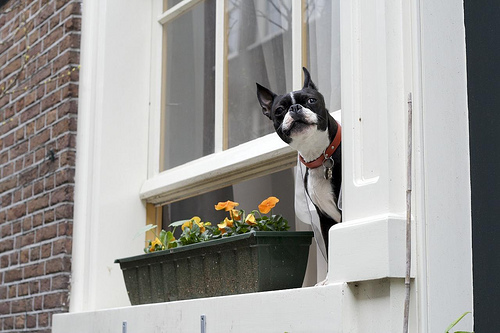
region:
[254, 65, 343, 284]
a black and white boston terrier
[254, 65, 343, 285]
a dog wearing a red collar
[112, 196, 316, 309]
a green planting box filled with flowers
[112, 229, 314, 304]
a green planting box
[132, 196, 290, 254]
orange planted ornamental flowers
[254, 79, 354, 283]
a black and white dog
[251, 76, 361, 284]
a dog looking out the window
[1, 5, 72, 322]
bricks on the building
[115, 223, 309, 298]
a black planter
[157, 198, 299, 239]
yellow flower in the window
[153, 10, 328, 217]
the window on the building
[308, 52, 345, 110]
white curtains inside the window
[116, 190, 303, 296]
a planter in the window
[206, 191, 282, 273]
Orange flowers in a green container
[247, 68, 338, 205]
Boston Terrier with it's head out the window.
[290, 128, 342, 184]
Red dog collar with a silver tag.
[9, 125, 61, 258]
Red brick on side of building.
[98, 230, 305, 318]
Long plastic flower box sitting on window sill.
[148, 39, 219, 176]
Glass window pane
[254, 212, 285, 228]
Green leaves on flowering plant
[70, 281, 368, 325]
Window ledge.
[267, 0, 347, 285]
Sheer white curtain behind window.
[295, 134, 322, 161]
White fur.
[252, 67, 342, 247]
black and white dog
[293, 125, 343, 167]
the dogs red collar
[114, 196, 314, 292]
flowers in a window sil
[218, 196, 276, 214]
the orange flowers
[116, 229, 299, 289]
the green plant holder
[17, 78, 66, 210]
the brick wall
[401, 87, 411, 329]
the stick against the window frame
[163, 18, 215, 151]
the glass in the window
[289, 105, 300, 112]
the dogs black nose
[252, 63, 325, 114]
both of the dogs ears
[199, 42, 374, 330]
the dog is looking out the window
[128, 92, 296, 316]
the window is open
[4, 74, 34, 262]
the bricks are red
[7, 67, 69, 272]
the wall is bricked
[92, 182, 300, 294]
flowers planted on a pot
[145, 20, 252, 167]
curtains inside the window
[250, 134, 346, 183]
the dog is wearing a collar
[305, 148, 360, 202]
the collar is red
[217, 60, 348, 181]
the dog is black and white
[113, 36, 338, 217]
the window pane is white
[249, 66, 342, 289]
The black and white dog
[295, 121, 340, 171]
The red collar on the dog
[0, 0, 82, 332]
The brick portion of the building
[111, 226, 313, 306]
The planter with the flowers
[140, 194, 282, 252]
The orange flowers in the planter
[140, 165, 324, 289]
The open window the dog is in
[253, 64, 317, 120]
The ears of the dog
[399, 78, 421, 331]
The stick next to the dog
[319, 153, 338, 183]
The metal tags on the dogs collar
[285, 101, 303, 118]
The nose of the dog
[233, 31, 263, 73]
part of a window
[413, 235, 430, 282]
part of a wall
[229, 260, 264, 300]
part of a vase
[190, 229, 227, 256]
edge of a vase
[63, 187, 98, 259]
edge of a vase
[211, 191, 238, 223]
part of a flower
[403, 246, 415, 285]
part of a stick